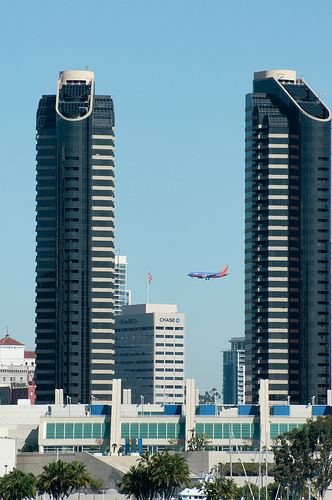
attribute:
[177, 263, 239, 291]
plane — blue, red, tiny, small, flying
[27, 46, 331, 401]
buildings — black, tall, long, white, grey and blue, red, brick, white, blue, white and grey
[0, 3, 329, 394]
sky — clear, big, open, blue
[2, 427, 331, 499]
trees — short, green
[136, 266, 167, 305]
flag — national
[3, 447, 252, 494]
trees — palm, green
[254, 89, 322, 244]
building — large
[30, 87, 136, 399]
building — large